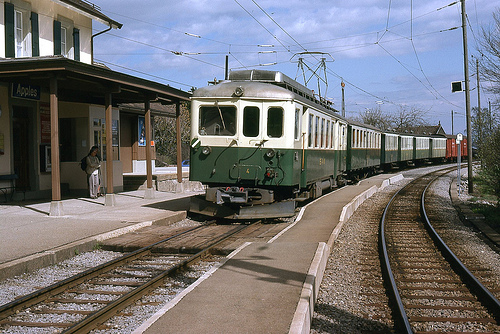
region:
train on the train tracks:
[188, 52, 318, 232]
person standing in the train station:
[80, 138, 104, 205]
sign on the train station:
[9, 78, 46, 105]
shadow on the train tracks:
[111, 225, 203, 284]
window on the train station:
[52, 12, 81, 57]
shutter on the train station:
[27, 14, 42, 59]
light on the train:
[232, 79, 253, 100]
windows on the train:
[238, 103, 290, 143]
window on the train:
[197, 98, 237, 142]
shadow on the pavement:
[229, 245, 311, 299]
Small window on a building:
[49, 15, 86, 58]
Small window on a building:
[8, 6, 53, 58]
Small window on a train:
[265, 102, 287, 143]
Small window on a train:
[240, 101, 265, 140]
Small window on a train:
[192, 100, 242, 142]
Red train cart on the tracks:
[444, 126, 471, 158]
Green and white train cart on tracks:
[431, 131, 446, 161]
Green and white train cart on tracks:
[414, 130, 431, 165]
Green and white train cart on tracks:
[398, 128, 418, 180]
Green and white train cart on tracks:
[382, 118, 402, 166]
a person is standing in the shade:
[83, 145, 103, 202]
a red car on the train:
[446, 134, 468, 160]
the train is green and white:
[186, 73, 449, 186]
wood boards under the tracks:
[4, 304, 111, 331]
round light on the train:
[232, 86, 245, 97]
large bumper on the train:
[190, 196, 294, 219]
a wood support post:
[46, 83, 61, 200]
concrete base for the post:
[48, 200, 63, 215]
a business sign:
[11, 83, 43, 100]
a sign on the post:
[448, 78, 471, 93]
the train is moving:
[180, 77, 458, 184]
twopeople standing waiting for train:
[73, 129, 130, 209]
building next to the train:
[6, 2, 160, 212]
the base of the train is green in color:
[201, 147, 319, 187]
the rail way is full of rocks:
[406, 235, 470, 332]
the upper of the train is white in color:
[285, 112, 358, 148]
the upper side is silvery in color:
[218, 73, 316, 97]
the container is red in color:
[453, 135, 472, 154]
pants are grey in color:
[84, 172, 107, 196]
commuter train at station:
[141, 35, 493, 235]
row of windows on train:
[261, 110, 461, 158]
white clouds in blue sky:
[281, 5, 410, 73]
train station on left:
[1, 21, 186, 255]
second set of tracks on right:
[374, 185, 459, 330]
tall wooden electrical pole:
[445, 10, 495, 136]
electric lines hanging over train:
[230, 18, 332, 72]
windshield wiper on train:
[202, 100, 232, 132]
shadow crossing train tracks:
[168, 227, 323, 320]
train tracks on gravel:
[3, 283, 126, 332]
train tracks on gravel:
[46, 261, 176, 292]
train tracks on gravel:
[107, 241, 210, 275]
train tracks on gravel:
[349, 294, 498, 332]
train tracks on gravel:
[349, 230, 489, 257]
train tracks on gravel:
[350, 203, 464, 229]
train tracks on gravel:
[357, 204, 489, 329]